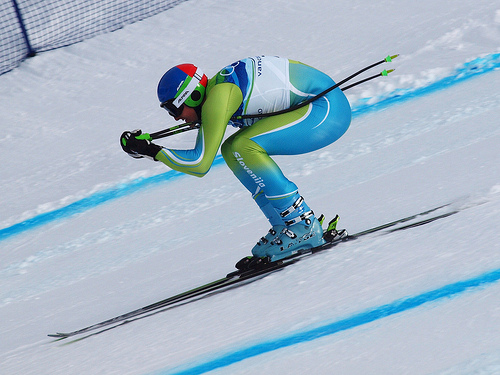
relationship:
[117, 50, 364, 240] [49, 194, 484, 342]
lady on board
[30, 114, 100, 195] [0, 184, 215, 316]
floor covered of snow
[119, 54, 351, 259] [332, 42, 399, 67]
lady holding stick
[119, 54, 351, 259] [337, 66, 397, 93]
lady holding stick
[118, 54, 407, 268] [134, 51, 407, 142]
he holding poles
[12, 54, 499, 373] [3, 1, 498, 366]
lines in snow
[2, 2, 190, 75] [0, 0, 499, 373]
fence outside course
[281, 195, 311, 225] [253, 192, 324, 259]
white snaps on boots